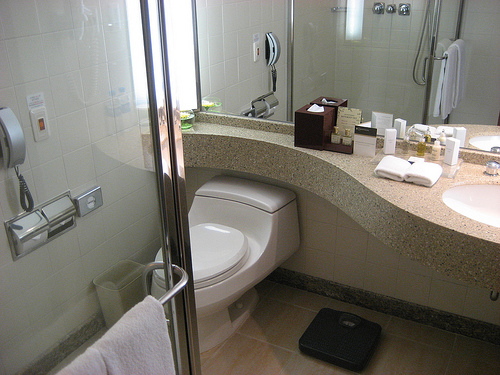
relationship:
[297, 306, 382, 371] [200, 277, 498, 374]
scale on top of floor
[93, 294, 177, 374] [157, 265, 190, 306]
towel hanging on towel rack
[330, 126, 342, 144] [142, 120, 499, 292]
perfume on top of counter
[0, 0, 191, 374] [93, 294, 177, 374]
shower door with towel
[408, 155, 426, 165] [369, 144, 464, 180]
soap on top of plate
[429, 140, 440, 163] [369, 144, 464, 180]
hair product on top of plate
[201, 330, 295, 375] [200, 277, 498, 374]
tile on top of ground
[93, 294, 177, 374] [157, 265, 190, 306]
towel hanging from towel rack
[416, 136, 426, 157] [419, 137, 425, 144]
bottle with top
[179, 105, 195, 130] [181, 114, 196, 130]
bowl with liquid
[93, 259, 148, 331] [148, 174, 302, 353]
trashcan next to toilet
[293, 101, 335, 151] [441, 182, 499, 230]
tissue box on side of sink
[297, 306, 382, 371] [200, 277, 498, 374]
scale laying on floor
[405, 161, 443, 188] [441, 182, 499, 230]
towel laying on sink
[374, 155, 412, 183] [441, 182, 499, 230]
towel laying on sink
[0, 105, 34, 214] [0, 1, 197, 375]
telephone hanging on wall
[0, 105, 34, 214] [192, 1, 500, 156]
telephone reflected in mirror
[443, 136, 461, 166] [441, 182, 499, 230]
lotion on side of sink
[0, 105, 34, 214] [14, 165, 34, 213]
telephone has cord